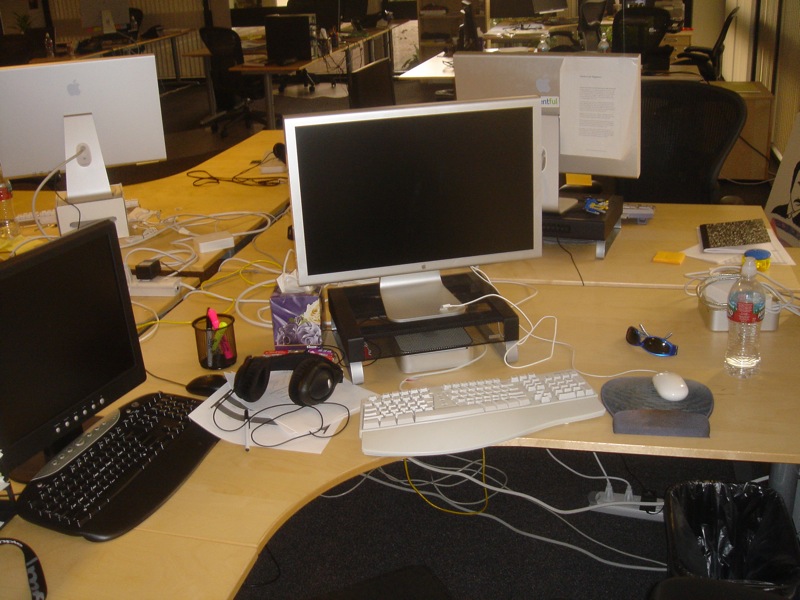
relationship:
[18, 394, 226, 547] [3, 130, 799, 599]
keyboard on desk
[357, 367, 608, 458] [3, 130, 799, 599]
keyboard on desk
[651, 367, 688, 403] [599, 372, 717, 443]
mouse on mousepad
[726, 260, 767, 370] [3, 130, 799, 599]
water bottle on top of desk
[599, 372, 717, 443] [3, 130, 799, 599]
mousepad on top of desk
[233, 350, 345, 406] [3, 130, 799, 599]
headphones are on top of desk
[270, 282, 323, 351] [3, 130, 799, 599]
kleenex box on top of desk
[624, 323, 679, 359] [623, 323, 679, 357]
pair of sunglasses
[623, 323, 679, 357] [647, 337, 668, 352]
sunglasses with lenses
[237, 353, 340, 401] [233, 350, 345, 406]
pair of earphones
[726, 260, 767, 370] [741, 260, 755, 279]
bottle of water with lid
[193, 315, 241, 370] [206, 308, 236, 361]
container with highlighter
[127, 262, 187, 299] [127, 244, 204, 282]
powerstrip with cords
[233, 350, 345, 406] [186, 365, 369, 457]
headset on top of paper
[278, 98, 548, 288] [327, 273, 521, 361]
monitor on top of stand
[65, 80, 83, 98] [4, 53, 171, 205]
apple logo on monitor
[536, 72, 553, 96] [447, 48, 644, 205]
apple logo on monitor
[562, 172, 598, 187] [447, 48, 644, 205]
post-it on monitor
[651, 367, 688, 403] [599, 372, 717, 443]
mouse on pad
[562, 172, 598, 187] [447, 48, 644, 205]
piece of paper on monitor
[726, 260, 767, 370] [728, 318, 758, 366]
bottle of spring water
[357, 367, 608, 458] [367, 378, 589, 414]
keyboard with ten key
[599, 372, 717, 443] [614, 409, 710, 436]
mousepad with wrist rest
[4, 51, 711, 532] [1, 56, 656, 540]
collection of work stations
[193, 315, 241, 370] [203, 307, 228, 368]
cup for storing pens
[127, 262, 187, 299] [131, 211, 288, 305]
surge protector for electricity